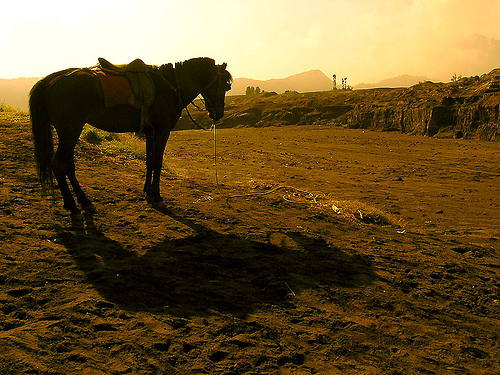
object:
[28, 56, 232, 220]
horse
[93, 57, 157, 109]
saddle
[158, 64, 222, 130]
harness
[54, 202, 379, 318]
shadow of horse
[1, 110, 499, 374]
dirt ground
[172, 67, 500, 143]
rocky edge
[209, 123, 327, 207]
rope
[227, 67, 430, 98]
mountains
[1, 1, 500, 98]
far distance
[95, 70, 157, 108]
blanket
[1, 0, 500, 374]
landscape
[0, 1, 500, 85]
sky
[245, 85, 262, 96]
tree like growths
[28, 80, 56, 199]
horse tail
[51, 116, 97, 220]
two back legs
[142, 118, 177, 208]
two front legs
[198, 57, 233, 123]
head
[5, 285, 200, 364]
footprints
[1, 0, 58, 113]
light from sun